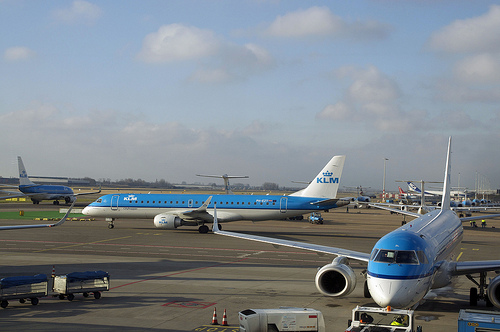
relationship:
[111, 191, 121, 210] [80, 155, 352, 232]
door attached to airplanes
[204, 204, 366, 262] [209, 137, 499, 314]
wing attached to plane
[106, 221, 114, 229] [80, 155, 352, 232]
landing gear of airplanes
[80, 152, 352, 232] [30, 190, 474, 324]
airplanes parked on tarmac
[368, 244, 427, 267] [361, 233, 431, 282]
window across cockpit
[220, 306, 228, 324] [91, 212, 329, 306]
traffic cone on tarmac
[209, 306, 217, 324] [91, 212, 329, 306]
cone on tarmac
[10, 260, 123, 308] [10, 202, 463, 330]
luggage carts on tarmac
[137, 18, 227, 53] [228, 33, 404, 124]
cloud in sky.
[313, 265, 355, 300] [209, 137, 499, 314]
engine on plane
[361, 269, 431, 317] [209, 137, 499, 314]
nose on plane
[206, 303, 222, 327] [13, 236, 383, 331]
cone on tarmac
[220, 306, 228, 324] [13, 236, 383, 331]
traffic cone on tarmac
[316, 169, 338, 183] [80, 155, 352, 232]
logo on airplanes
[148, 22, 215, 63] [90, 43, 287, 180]
cloud in sky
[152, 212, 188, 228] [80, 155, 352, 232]
engine on airplanes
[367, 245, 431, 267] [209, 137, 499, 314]
window on plane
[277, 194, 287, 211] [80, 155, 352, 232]
door on side of airplanes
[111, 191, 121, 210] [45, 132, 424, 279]
door on side of plane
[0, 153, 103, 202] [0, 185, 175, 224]
plane on runway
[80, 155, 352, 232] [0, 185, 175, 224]
airplanes on runway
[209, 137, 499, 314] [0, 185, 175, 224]
plane on runway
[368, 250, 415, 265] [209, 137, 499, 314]
windshield on plane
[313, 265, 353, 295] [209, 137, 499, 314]
engine of plane